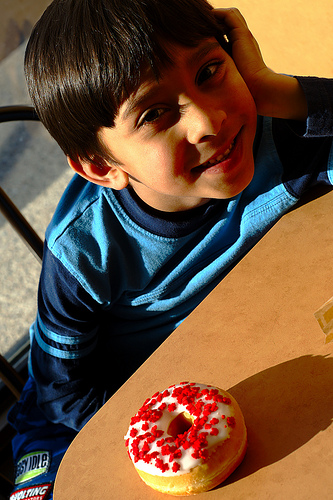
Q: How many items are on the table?
A: One.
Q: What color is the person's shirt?
A: Blue.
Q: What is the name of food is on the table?
A: Doughnut.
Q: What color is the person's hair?
A: Black.